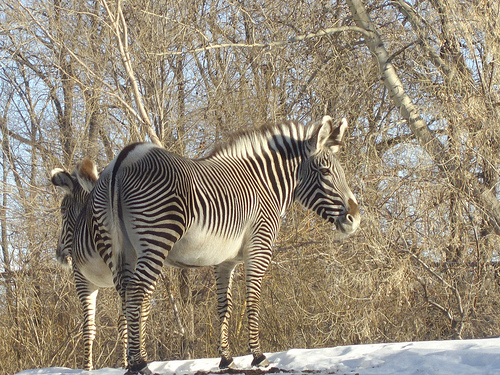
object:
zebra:
[88, 114, 363, 375]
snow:
[276, 352, 294, 372]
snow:
[300, 345, 325, 366]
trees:
[308, 0, 368, 240]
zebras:
[50, 154, 122, 369]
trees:
[374, 0, 500, 212]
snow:
[350, 343, 431, 362]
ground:
[162, 357, 218, 372]